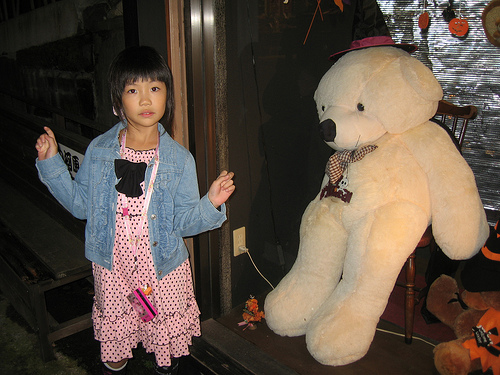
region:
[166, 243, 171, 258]
part of a jacket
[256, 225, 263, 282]
part of a cable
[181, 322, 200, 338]
part of a dress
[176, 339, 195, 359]
edge of a dress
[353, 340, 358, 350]
part of a doll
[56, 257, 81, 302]
part of a bench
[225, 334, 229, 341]
edge of a bench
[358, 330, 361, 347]
part of a leg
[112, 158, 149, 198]
black bow on girl's dress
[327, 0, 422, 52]
witch's hat on teddy bear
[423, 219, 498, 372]
teddy bear dressed as witch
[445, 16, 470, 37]
orange jack-o-lantern decoration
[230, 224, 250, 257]
electrical outlet with a cord plugged into it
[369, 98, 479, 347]
chair under large teddy bear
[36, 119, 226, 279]
jean jacket on girl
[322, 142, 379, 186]
brown gingham ribbon on teddy bear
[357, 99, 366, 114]
big black button eye on bear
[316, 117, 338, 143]
big brown nose on bear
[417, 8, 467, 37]
hanging pumpkin decorations on window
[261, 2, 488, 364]
stuffed bear on chair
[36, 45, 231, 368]
girl in blue jacket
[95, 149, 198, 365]
pink dress with polka dots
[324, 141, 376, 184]
plaid ribbon on bear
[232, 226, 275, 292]
wire plugged into wall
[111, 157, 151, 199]
black bow on dress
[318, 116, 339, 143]
black nose on bear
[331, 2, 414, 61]
hat on bear's head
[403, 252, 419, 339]
wood leg of chair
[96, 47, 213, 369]
A young girl wearing a pink dress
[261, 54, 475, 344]
A large tan colored bear on a chair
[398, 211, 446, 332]
The chair is made of wood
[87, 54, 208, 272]
The girl is wearing a denim jacket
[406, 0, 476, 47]
Jack o lanterns on the wall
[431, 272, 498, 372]
There is a brown bear on the floor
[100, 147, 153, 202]
A bow that is black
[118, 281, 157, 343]
This is a small change purse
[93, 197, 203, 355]
The dress is pink with black polka dots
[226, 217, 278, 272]
A cord plugged into the outlet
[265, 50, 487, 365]
white plush stuffed bear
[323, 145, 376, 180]
gingham ribbon on bear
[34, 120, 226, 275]
light blue denim jacket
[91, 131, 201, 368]
pink polka dot dress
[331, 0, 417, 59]
witch hat on bear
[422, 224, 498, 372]
brown stuffed bear on shelf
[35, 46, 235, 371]
girl wearing pink dress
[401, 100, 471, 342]
brown wooden chair on shelf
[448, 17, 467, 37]
orange decoration on wall